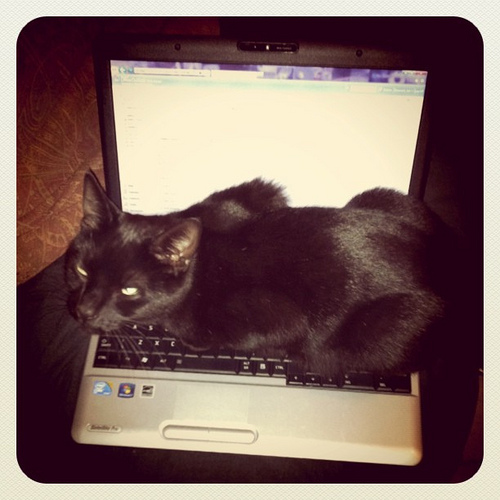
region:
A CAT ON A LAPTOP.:
[50, 169, 483, 384]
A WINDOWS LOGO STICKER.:
[114, 380, 136, 403]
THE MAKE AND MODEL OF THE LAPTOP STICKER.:
[85, 420, 127, 435]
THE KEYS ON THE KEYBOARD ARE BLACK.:
[97, 340, 159, 367]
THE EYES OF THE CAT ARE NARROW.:
[68, 253, 152, 307]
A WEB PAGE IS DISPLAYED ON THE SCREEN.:
[106, 56, 428, 214]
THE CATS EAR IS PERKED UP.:
[137, 218, 213, 269]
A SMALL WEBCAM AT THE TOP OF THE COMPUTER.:
[236, 35, 307, 60]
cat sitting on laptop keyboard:
[66, 38, 446, 463]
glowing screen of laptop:
[97, 38, 437, 216]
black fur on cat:
[65, 170, 448, 375]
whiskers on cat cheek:
[105, 317, 162, 369]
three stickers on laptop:
[91, 380, 153, 399]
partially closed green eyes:
[71, 263, 138, 297]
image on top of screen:
[112, 60, 429, 82]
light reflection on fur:
[336, 210, 408, 295]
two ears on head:
[78, 169, 204, 267]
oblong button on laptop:
[156, 421, 258, 443]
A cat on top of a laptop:
[58, 28, 463, 469]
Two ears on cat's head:
[67, 162, 203, 262]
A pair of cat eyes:
[67, 251, 139, 306]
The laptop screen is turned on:
[90, 30, 440, 220]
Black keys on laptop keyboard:
[86, 312, 416, 402]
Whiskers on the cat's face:
[35, 265, 155, 365]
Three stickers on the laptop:
[80, 370, 160, 410]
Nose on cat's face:
[70, 295, 100, 325]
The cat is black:
[50, 160, 470, 397]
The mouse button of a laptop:
[155, 415, 265, 452]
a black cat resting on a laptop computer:
[58, 45, 482, 467]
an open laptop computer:
[71, 46, 439, 466]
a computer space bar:
[173, 355, 240, 374]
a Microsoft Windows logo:
[116, 382, 135, 399]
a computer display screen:
[109, 59, 428, 216]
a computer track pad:
[176, 380, 251, 425]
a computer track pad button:
[163, 423, 255, 442]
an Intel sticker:
[91, 378, 113, 397]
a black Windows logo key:
[136, 352, 152, 368]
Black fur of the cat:
[231, 245, 275, 277]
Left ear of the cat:
[167, 220, 201, 266]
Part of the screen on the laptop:
[118, 64, 418, 171]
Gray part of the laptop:
[223, 392, 251, 417]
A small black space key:
[176, 357, 239, 374]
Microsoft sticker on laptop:
[115, 380, 135, 399]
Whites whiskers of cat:
[116, 331, 138, 353]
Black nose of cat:
[79, 300, 95, 317]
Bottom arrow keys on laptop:
[290, 372, 336, 387]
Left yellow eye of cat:
[121, 283, 137, 298]